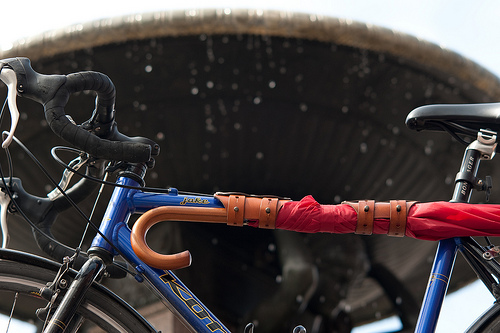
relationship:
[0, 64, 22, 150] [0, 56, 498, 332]
brake handle of bicycle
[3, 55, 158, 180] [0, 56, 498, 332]
handle of bicycle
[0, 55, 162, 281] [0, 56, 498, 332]
handle of bicycle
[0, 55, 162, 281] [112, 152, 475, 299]
handle of umbrella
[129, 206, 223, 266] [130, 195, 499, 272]
handle of umbrella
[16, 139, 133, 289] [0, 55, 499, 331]
wires on bicycle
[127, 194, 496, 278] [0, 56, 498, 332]
umbrella strapped to bicycle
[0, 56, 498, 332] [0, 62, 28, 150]
bicycle has handbreak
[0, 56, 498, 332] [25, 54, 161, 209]
bicycle has handle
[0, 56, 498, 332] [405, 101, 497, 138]
bicycle has seat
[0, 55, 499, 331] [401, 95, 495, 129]
bicycle has seat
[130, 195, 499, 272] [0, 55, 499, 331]
umbrella attached to bicycle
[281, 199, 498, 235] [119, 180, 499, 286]
cloth on umbrella